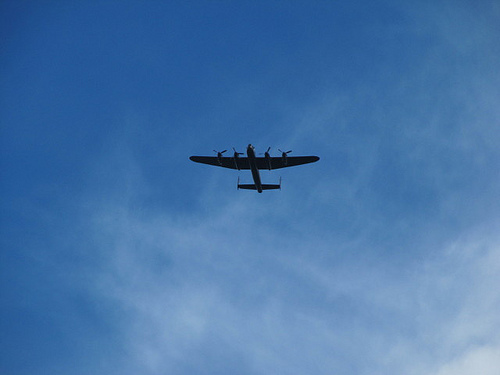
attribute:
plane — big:
[169, 135, 336, 196]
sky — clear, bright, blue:
[0, 1, 498, 373]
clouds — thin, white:
[42, 122, 188, 369]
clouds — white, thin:
[391, 224, 491, 322]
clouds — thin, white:
[117, 206, 471, 352]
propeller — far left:
[277, 146, 294, 158]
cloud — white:
[157, 274, 194, 309]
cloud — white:
[273, 277, 330, 311]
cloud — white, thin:
[306, 192, 362, 228]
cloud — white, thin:
[239, 213, 292, 256]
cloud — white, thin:
[167, 166, 227, 210]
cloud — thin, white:
[182, 189, 222, 211]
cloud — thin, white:
[269, 196, 324, 219]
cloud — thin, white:
[238, 217, 280, 237]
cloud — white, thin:
[190, 197, 234, 228]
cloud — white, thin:
[236, 204, 278, 230]